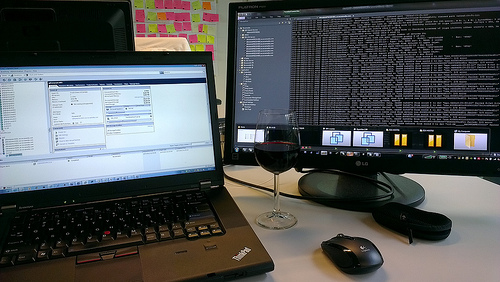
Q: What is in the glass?
A: Wine.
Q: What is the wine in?
A: A wine glass.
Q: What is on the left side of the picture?
A: A laptop.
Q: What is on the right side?
A: A big monitor.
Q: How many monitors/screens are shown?
A: Two.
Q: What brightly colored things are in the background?
A: Post-it notes.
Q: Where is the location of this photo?
A: An office.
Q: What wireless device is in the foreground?
A: A mouse.